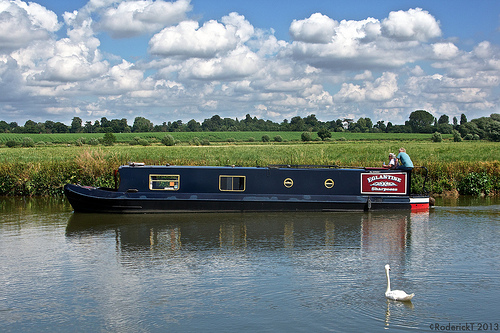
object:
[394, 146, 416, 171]
people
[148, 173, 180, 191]
window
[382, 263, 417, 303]
duck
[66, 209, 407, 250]
shadow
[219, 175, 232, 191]
window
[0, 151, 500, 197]
grass water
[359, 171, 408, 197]
sign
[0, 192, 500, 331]
calm water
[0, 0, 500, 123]
sky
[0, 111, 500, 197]
greenery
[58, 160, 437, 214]
boat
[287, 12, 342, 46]
clouds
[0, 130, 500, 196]
fields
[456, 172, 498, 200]
weeds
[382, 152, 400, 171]
people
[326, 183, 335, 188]
window